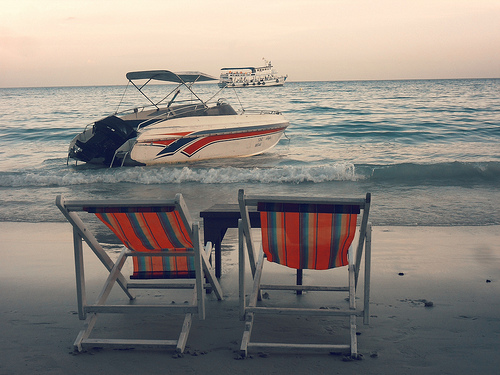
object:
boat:
[66, 69, 293, 169]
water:
[0, 78, 498, 222]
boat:
[217, 57, 289, 89]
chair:
[53, 192, 225, 354]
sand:
[0, 221, 499, 372]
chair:
[236, 188, 372, 359]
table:
[198, 204, 303, 296]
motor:
[66, 115, 138, 165]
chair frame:
[54, 193, 223, 356]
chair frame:
[235, 188, 372, 359]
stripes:
[180, 126, 286, 160]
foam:
[0, 159, 355, 187]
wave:
[0, 159, 499, 190]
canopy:
[125, 69, 219, 82]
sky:
[0, 0, 498, 89]